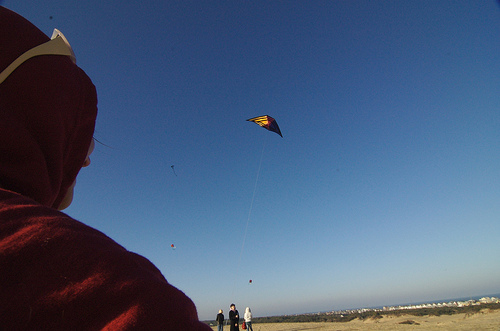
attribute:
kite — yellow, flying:
[245, 115, 283, 137]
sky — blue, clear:
[0, 0, 499, 328]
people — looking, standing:
[216, 304, 255, 331]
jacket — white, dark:
[244, 307, 254, 321]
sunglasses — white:
[0, 28, 77, 86]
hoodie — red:
[1, 3, 215, 330]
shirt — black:
[230, 311, 241, 324]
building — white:
[480, 295, 492, 303]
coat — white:
[242, 305, 254, 322]